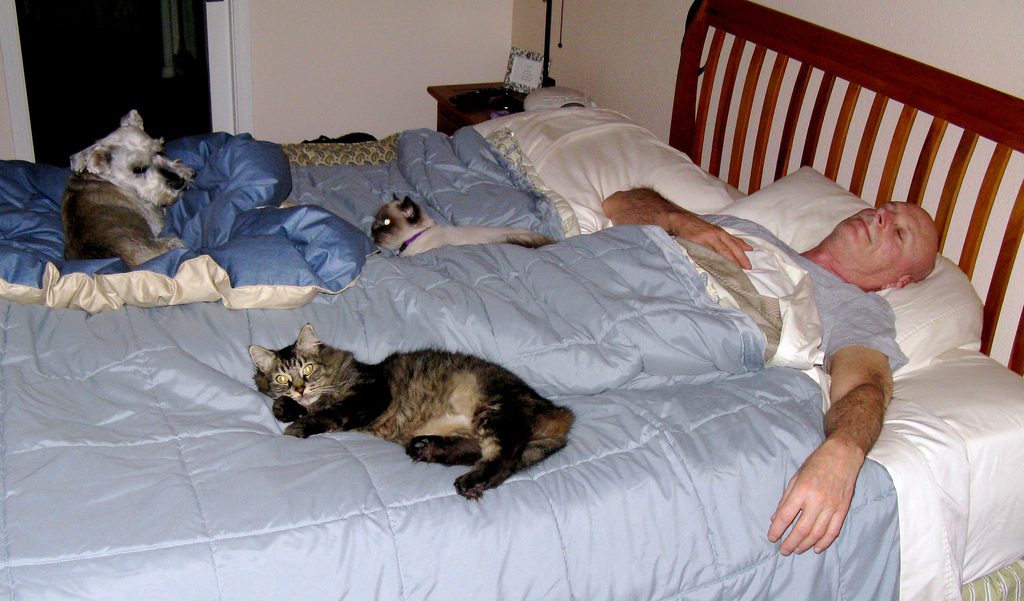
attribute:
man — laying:
[586, 166, 969, 558]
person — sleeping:
[0, 186, 939, 557]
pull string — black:
[525, 11, 606, 55]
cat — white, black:
[227, 336, 722, 521]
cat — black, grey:
[250, 314, 586, 524]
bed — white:
[45, 121, 970, 539]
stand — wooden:
[413, 40, 604, 140]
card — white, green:
[491, 47, 555, 95]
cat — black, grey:
[231, 300, 583, 513]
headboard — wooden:
[665, 1, 1021, 381]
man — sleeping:
[607, 177, 969, 548]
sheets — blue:
[5, 128, 824, 594]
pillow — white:
[465, 100, 745, 240]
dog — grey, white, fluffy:
[242, 322, 650, 510]